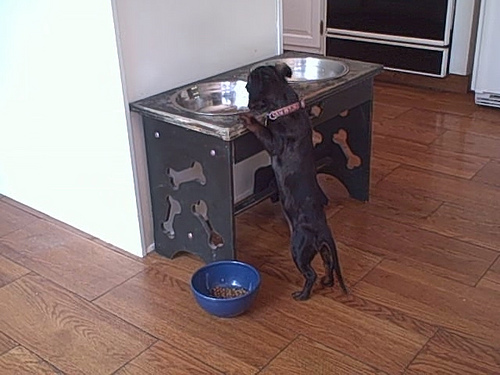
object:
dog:
[243, 60, 347, 302]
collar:
[263, 100, 305, 121]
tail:
[321, 240, 349, 293]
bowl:
[192, 260, 263, 318]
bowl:
[173, 81, 257, 117]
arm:
[242, 111, 284, 154]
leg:
[291, 223, 323, 304]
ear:
[278, 62, 292, 78]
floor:
[0, 81, 500, 374]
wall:
[0, 2, 149, 259]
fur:
[281, 127, 308, 182]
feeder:
[129, 53, 386, 264]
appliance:
[322, 2, 458, 44]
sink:
[251, 55, 351, 84]